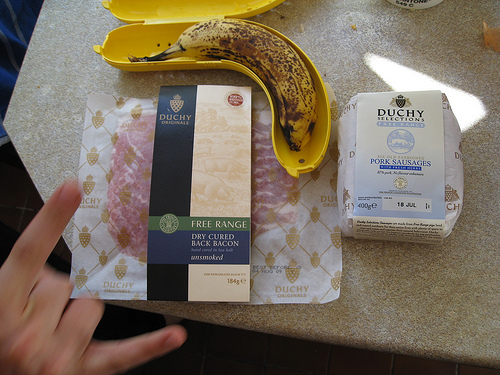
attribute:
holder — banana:
[108, 15, 203, 72]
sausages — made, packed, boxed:
[356, 83, 491, 273]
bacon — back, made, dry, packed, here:
[110, 79, 276, 211]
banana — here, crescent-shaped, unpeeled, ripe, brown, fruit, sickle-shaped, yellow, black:
[191, 31, 351, 118]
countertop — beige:
[36, 34, 91, 113]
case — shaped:
[150, 14, 225, 79]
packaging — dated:
[328, 122, 408, 206]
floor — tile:
[10, 11, 51, 47]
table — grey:
[47, 82, 77, 127]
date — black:
[382, 191, 435, 209]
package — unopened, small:
[362, 98, 470, 232]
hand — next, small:
[6, 221, 142, 374]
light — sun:
[377, 54, 458, 99]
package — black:
[138, 108, 231, 259]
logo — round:
[142, 206, 184, 231]